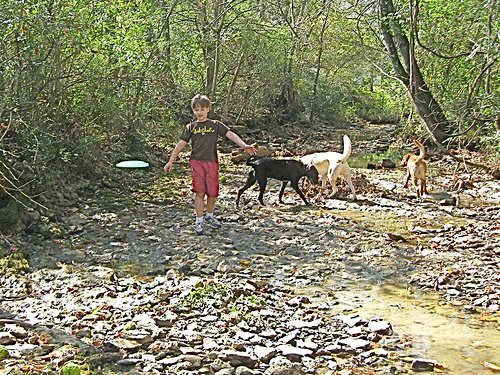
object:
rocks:
[102, 306, 135, 320]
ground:
[13, 323, 97, 344]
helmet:
[181, 118, 231, 165]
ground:
[332, 329, 387, 373]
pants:
[187, 156, 219, 198]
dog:
[398, 136, 428, 195]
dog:
[277, 134, 357, 196]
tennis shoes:
[190, 216, 208, 234]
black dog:
[233, 155, 323, 203]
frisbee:
[112, 159, 150, 171]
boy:
[162, 90, 258, 235]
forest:
[132, 34, 172, 84]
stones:
[118, 327, 148, 340]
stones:
[164, 328, 185, 341]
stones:
[180, 343, 198, 354]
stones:
[156, 356, 178, 366]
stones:
[115, 357, 143, 365]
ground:
[128, 330, 292, 362]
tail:
[414, 137, 431, 162]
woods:
[3, 3, 484, 370]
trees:
[377, 0, 498, 148]